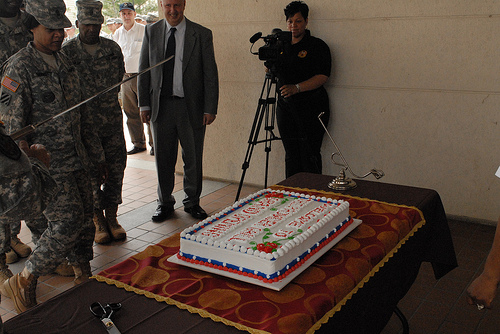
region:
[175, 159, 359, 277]
red and white cake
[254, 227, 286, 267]
red flowers on cake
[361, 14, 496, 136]
white wall near woman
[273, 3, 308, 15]
woman has black hair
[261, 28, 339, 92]
woman has black shirt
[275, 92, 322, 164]
woman has black pants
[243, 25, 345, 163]
woman is behind camera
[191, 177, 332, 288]
cake on red cloth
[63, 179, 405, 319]
red cloth on black table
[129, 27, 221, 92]
man has grey coat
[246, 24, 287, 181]
camera on tripod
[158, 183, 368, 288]
decorated cake with frosting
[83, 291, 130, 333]
scissors laying on table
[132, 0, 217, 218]
man in grey suit with tie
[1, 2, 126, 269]
American soldiers in uniforms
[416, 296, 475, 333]
ceramic tile floor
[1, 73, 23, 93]
American flag patch on uniform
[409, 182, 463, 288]
brown tablecloth on table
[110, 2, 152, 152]
man in white shirt and blue hat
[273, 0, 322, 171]
woman in black using camera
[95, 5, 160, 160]
people standing outside in the sun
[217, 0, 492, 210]
photographer against tan stone wall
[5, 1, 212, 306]
man in suit and soldiers in military uniforms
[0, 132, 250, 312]
tiled floor under boots and shoes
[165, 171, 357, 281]
rectangular cake in patriotic colors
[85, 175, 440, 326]
red mat with circles over dark tablecloth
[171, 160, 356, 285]
beads of icing around top and bottom of cake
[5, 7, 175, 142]
thin and long metal blade across people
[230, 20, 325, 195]
woman behind tripod with camera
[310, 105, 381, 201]
slanted stand in metal base by cake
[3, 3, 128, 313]
Military people are looking at the cake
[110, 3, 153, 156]
The man is wearing a black hat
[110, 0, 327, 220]
Three civilians are dressed in casual clothing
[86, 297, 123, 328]
A pair of scissors are on the table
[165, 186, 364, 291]
The a cake is red, white, green, and blue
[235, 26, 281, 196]
A woman is using the camera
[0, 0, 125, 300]
The military are in uniform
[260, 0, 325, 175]
a woman using the camera is wearing black, and gold clothes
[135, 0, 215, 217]
One man is wearing a suite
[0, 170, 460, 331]
The table cloth is brown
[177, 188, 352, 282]
cake decorated in red, white and blue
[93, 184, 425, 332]
patterned tablecloth under the cake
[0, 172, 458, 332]
black tablecloth covering the whole table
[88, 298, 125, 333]
black handled scissors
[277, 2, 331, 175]
a woman operating a video camera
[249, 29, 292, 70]
black video camera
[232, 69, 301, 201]
tripod the camera sits on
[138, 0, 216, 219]
a man in a suit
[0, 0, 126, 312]
a group of soldiers in uniform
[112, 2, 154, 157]
a man looking in through the doorway